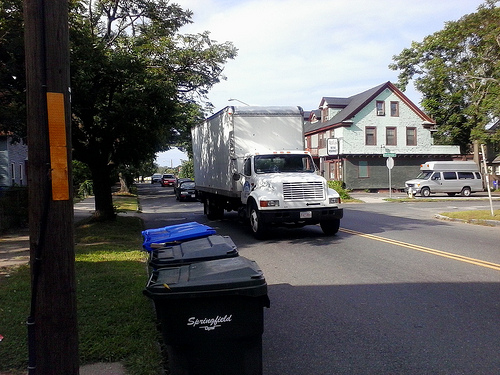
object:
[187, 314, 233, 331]
white letters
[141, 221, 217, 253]
trash can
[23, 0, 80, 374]
pole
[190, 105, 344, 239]
truck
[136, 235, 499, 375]
road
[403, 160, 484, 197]
van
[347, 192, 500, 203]
side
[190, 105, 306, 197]
big box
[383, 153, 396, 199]
sign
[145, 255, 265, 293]
lids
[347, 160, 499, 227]
parking lot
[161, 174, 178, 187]
mini van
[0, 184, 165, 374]
side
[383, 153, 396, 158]
street sign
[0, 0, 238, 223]
tree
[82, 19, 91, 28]
green leaves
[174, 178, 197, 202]
car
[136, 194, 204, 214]
down street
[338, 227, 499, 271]
double line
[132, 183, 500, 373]
street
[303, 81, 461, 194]
building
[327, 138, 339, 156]
sign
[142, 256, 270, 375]
trash can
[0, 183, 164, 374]
street curb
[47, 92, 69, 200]
gold flag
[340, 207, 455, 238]
shadow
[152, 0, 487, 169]
sky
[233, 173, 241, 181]
mirror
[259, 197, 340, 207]
headlight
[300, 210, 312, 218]
licence plate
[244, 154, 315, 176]
windshield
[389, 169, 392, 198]
pole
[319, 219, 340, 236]
front wheels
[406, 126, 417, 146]
windows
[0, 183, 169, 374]
grass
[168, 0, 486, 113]
cloud